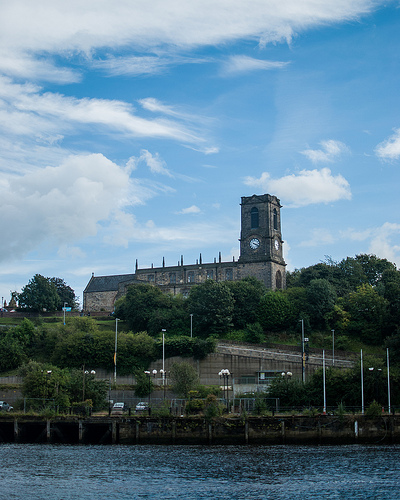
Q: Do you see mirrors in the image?
A: No, there are no mirrors.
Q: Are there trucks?
A: No, there are no trucks.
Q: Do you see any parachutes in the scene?
A: No, there are no parachutes.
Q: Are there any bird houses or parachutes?
A: No, there are no parachutes or bird houses.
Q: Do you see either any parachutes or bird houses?
A: No, there are no parachutes or bird houses.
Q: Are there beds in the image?
A: No, there are no beds.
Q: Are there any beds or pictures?
A: No, there are no beds or pictures.